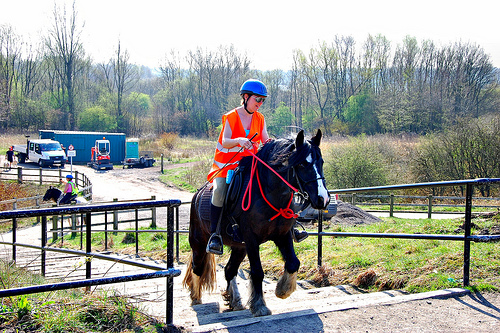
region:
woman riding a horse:
[164, 65, 341, 318]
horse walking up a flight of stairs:
[175, 132, 340, 324]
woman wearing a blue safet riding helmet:
[232, 77, 276, 123]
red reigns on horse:
[246, 140, 296, 222]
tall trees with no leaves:
[10, 46, 490, 96]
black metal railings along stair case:
[12, 180, 189, 329]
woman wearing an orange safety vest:
[196, 107, 276, 182]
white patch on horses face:
[305, 140, 338, 215]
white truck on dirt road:
[10, 133, 68, 163]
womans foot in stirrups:
[200, 218, 233, 261]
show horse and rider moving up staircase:
[165, 67, 369, 319]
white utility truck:
[0, 126, 67, 173]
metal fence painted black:
[0, 186, 190, 329]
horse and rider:
[23, 170, 103, 235]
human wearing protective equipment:
[173, 65, 282, 258]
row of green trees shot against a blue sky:
[105, 1, 487, 163]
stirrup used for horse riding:
[200, 225, 230, 263]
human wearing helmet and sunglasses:
[238, 74, 273, 119]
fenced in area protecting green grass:
[32, 175, 489, 309]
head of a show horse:
[270, 112, 350, 231]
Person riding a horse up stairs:
[146, 91, 386, 331]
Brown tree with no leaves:
[457, 38, 494, 122]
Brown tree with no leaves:
[410, 34, 452, 130]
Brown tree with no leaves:
[360, 33, 395, 156]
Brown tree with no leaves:
[318, 24, 369, 148]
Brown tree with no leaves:
[273, 41, 340, 152]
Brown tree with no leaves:
[175, 47, 228, 152]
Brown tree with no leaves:
[117, 55, 227, 149]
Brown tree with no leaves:
[63, 24, 143, 144]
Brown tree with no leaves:
[2, 26, 67, 138]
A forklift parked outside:
[89, 140, 111, 170]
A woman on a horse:
[183, 79, 328, 315]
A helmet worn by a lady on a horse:
[240, 79, 267, 96]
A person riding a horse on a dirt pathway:
[45, 172, 90, 232]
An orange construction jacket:
[209, 109, 264, 179]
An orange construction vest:
[207, 108, 265, 181]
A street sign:
[67, 145, 75, 169]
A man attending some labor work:
[2, 145, 15, 173]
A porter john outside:
[123, 138, 139, 163]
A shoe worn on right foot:
[205, 230, 222, 252]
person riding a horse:
[185, 63, 335, 282]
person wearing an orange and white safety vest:
[210, 71, 277, 188]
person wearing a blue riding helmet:
[207, 63, 275, 187]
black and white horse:
[204, 140, 339, 309]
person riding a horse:
[42, 164, 103, 240]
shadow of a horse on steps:
[189, 287, 336, 330]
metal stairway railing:
[15, 190, 182, 317]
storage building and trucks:
[37, 119, 149, 164]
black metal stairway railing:
[315, 170, 493, 275]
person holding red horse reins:
[208, 80, 318, 225]